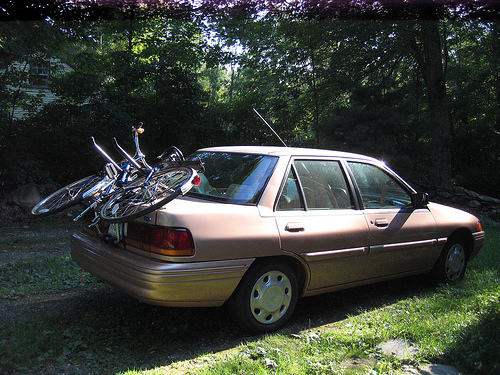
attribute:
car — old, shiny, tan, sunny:
[69, 145, 484, 333]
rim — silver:
[249, 269, 292, 323]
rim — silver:
[443, 243, 465, 281]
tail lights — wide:
[82, 206, 194, 260]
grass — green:
[4, 220, 499, 374]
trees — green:
[0, 0, 499, 200]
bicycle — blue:
[30, 121, 201, 220]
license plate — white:
[103, 220, 128, 237]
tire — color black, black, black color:
[225, 256, 298, 332]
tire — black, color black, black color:
[431, 237, 467, 284]